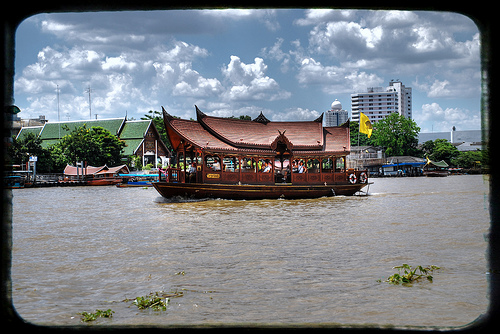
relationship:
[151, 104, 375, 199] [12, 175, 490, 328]
boat on water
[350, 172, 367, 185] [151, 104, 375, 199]
life rings on boat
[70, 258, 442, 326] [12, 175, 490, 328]
plants in water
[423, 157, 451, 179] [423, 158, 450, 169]
boat with a green roof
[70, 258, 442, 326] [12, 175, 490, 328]
plants floating in water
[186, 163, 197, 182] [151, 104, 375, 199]
person on boat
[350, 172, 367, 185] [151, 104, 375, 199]
life rings on side of boat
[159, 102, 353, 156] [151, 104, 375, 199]
roof of boat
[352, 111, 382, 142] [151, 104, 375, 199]
flag on boat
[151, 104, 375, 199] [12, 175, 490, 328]
boat floats on water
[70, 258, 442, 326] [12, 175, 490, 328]
plants floating on water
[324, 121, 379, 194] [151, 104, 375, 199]
back of boat